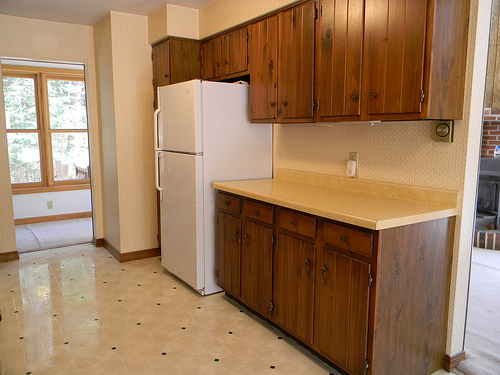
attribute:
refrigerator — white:
[151, 78, 277, 299]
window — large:
[3, 76, 89, 183]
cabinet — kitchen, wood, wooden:
[247, 3, 312, 124]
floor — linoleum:
[1, 243, 462, 373]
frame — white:
[2, 62, 95, 196]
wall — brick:
[484, 121, 500, 163]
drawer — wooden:
[319, 218, 377, 261]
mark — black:
[160, 349, 170, 358]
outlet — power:
[344, 148, 360, 179]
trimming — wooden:
[91, 237, 162, 264]